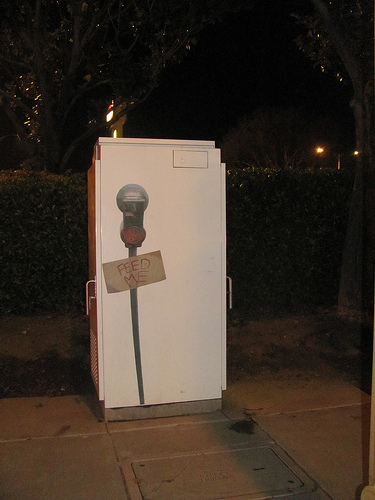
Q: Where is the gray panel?
A: On the sidewalk.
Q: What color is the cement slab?
A: Gray.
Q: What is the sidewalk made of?
A: Gray cement.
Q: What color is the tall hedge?
A: Green.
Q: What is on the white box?
A: A sign.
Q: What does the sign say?
A: Feed me.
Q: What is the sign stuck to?
A: Parking meter.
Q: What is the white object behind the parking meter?
A: White metal box.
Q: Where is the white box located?
A: Sidewalk.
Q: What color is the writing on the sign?
A: Red.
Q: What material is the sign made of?
A: Cardboard.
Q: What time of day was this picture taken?
A: Late evening.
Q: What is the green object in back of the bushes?
A: Trees.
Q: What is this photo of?
A: A refrigerator.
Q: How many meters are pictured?
A: One.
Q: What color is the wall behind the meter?
A: White.